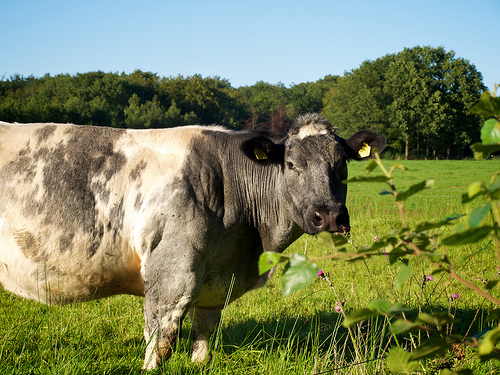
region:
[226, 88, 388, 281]
A cow's face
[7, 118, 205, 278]
The spots on a cow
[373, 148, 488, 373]
Leaves on a branch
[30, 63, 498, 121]
A row of trees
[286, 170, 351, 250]
A cow's snout and nostrils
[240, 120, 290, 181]
A Cow's right ear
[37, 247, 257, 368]
The legs of a cow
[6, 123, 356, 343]
A very large bovine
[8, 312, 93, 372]
Tall leaves of grass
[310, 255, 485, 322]
Some small pink flowers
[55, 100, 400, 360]
cow standing in meadow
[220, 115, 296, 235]
vertical wrinkles along neck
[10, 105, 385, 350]
large cow with grey markings across back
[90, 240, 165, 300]
rusty color behind thighs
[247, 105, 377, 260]
cow with head turned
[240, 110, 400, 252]
cow with large round nostrils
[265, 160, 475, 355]
tall stems with leaves and purple buds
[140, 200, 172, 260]
indentation at top of leg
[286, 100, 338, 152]
grey fuzzy hair on top of white crown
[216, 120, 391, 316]
tags inside each ear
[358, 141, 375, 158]
Tag in the cow's left ear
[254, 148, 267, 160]
The tag in the cow's right ear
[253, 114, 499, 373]
Out of focus plant in front of cow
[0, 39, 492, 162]
The trees behind the cow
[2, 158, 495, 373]
Grass field the cow is standing in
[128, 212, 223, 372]
The front legs of the cow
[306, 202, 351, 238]
The nose of the cow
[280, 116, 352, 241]
The head of the cow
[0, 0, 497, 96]
The sky above the trees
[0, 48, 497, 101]
The horizon line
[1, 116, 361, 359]
huge cow standing in grassy field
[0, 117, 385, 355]
huge cow looking at the camera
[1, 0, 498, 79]
the sky is clear of clouds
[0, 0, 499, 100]
the sky is light blue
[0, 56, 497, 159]
row of huge trees in the background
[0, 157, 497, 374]
the grass is bright green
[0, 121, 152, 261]
large black patch of fur on cow's back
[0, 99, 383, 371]
the cow has yellow tags in it's ears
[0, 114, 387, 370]
the huge cow is up in age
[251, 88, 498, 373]
the bush has small purple flowers on it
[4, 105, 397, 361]
Black and white cow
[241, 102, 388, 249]
Cow with yellow tags in its ears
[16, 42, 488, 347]
Cow in open field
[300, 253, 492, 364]
Small pink flowers growing in feild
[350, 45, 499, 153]
Trees with green leaves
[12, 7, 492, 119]
Blue sky and tree tops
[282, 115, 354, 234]
Cow's face with white spot on forehead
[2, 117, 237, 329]
Torso of a cow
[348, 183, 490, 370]
Plants growing in a field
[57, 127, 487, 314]
Cow in a pasture